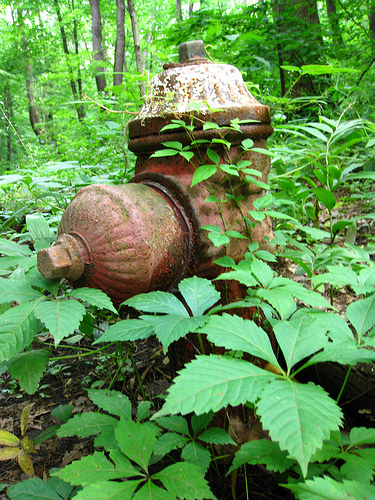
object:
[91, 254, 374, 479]
plants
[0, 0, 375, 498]
woods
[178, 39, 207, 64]
bolt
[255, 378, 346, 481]
leaves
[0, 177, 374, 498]
ground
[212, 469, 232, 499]
root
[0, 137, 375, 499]
road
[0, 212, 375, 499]
weed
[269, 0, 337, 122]
tree trunk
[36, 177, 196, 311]
valve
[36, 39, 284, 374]
fire hydrant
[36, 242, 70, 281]
bolt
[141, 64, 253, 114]
pant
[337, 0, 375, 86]
branch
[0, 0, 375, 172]
trees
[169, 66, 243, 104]
paint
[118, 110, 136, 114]
part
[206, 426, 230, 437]
edge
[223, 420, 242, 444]
part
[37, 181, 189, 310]
cap